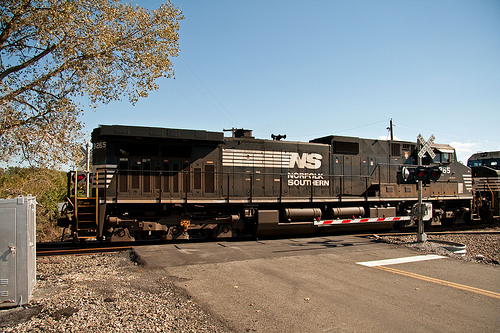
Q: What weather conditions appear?
A: It is clear.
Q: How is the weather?
A: It is clear.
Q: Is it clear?
A: Yes, it is clear.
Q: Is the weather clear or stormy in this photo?
A: It is clear.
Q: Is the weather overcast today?
A: No, it is clear.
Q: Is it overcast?
A: No, it is clear.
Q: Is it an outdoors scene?
A: Yes, it is outdoors.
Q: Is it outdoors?
A: Yes, it is outdoors.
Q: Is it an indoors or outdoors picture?
A: It is outdoors.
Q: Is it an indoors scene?
A: No, it is outdoors.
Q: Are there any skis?
A: No, there are no skis.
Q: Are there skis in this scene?
A: No, there are no skis.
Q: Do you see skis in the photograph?
A: No, there are no skis.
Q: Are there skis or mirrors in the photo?
A: No, there are no skis or mirrors.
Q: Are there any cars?
A: No, there are no cars.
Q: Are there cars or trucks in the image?
A: No, there are no cars or trucks.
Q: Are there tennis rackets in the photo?
A: No, there are no tennis rackets.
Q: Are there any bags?
A: No, there are no bags.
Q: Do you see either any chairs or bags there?
A: No, there are no bags or chairs.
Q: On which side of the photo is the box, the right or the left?
A: The box is on the left of the image.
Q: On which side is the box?
A: The box is on the left of the image.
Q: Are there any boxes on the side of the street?
A: Yes, there is a box on the side of the street.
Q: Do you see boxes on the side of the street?
A: Yes, there is a box on the side of the street.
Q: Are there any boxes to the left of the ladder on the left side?
A: Yes, there is a box to the left of the ladder.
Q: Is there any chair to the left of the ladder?
A: No, there is a box to the left of the ladder.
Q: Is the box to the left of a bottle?
A: No, the box is to the left of the ladder.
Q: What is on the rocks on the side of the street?
A: The box is on the rocks.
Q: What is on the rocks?
A: The box is on the rocks.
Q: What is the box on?
A: The box is on the rocks.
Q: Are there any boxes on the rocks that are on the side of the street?
A: Yes, there is a box on the rocks.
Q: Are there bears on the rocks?
A: No, there is a box on the rocks.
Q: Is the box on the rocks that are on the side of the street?
A: Yes, the box is on the rocks.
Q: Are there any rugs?
A: No, there are no rugs.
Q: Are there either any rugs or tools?
A: No, there are no rugs or tools.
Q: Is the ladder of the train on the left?
A: Yes, the ladder is on the left of the image.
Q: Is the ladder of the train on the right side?
A: No, the ladder is on the left of the image.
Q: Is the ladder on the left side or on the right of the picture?
A: The ladder is on the left of the image.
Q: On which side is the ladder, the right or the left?
A: The ladder is on the left of the image.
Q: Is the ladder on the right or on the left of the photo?
A: The ladder is on the left of the image.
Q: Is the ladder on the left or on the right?
A: The ladder is on the left of the image.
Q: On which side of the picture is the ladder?
A: The ladder is on the left of the image.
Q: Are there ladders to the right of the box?
A: Yes, there is a ladder to the right of the box.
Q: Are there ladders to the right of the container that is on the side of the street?
A: Yes, there is a ladder to the right of the box.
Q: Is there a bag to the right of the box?
A: No, there is a ladder to the right of the box.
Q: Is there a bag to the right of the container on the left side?
A: No, there is a ladder to the right of the box.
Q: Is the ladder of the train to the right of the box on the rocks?
A: Yes, the ladder is to the right of the box.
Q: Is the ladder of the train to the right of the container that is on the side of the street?
A: Yes, the ladder is to the right of the box.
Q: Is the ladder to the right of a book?
A: No, the ladder is to the right of the box.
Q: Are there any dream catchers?
A: No, there are no dream catchers.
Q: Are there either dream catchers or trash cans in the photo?
A: No, there are no dream catchers or trash cans.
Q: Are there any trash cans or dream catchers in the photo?
A: No, there are no dream catchers or trash cans.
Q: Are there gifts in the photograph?
A: No, there are no gifts.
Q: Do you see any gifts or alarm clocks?
A: No, there are no gifts or alarm clocks.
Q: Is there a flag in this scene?
A: No, there are no flags.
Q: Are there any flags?
A: No, there are no flags.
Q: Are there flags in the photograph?
A: No, there are no flags.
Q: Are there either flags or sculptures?
A: No, there are no flags or sculptures.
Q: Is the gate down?
A: Yes, the gate is down.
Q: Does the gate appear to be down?
A: Yes, the gate is down.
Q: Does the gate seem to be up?
A: No, the gate is down.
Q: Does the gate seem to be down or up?
A: The gate is down.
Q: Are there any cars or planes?
A: No, there are no cars or planes.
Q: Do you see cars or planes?
A: No, there are no cars or planes.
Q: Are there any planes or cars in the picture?
A: No, there are no cars or planes.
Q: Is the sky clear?
A: Yes, the sky is clear.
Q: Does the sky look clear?
A: Yes, the sky is clear.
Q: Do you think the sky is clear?
A: Yes, the sky is clear.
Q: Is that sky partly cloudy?
A: No, the sky is clear.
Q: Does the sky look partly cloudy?
A: No, the sky is clear.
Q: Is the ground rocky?
A: Yes, the ground is rocky.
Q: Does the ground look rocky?
A: Yes, the ground is rocky.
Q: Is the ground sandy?
A: No, the ground is rocky.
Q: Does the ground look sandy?
A: No, the ground is rocky.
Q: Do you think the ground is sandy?
A: No, the ground is rocky.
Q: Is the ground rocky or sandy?
A: The ground is rocky.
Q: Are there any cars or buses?
A: No, there are no cars or buses.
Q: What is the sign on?
A: The sign is on the pole.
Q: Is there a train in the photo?
A: Yes, there is a train.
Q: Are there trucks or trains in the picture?
A: Yes, there is a train.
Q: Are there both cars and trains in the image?
A: No, there is a train but no cars.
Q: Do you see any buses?
A: No, there are no buses.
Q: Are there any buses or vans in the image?
A: No, there are no buses or vans.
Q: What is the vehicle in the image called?
A: The vehicle is a train.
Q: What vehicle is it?
A: The vehicle is a train.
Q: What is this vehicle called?
A: That is a train.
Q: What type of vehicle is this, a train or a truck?
A: That is a train.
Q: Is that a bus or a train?
A: That is a train.